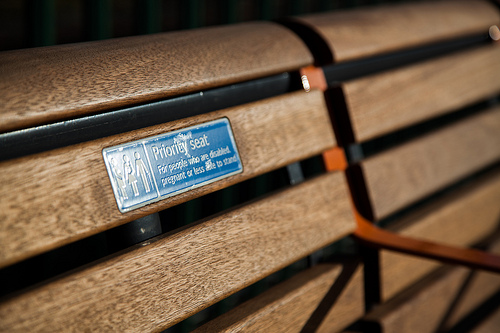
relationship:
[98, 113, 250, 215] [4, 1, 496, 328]
sign on a bench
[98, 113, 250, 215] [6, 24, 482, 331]
sign on bench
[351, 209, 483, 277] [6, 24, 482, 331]
armrest on bench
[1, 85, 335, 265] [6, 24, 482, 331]
slat on bench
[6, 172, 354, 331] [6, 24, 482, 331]
slat on bench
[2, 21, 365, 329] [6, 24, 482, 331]
backrest on bench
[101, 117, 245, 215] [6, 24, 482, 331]
sign on bench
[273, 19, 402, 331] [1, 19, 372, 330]
joint between bench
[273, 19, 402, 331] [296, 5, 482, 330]
joint between bench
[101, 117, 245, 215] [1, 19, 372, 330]
sign in bench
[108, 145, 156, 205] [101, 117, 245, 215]
drawing on sign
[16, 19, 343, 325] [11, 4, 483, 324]
backplate of seats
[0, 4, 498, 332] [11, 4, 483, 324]
backplate of seats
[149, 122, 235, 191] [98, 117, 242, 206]
letters in sign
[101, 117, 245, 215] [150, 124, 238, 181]
sign with letters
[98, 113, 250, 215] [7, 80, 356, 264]
sign on bench slat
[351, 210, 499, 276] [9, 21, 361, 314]
armrest of bench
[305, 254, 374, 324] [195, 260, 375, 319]
shadow cast on bench slat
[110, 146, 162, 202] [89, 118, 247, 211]
logo on sign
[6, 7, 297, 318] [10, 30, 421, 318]
background behind bench